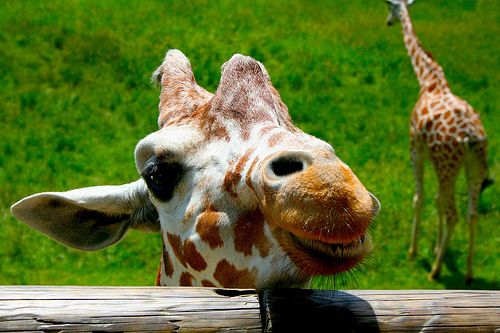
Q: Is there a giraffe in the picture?
A: Yes, there is a giraffe.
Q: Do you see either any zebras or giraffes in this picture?
A: Yes, there is a giraffe.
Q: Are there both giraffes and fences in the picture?
A: Yes, there are both a giraffe and a fence.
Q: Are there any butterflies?
A: No, there are no butterflies.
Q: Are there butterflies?
A: No, there are no butterflies.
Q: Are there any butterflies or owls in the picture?
A: No, there are no butterflies or owls.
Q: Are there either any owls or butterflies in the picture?
A: No, there are no butterflies or owls.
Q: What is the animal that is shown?
A: The animal is a giraffe.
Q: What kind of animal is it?
A: The animal is a giraffe.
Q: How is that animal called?
A: That is a giraffe.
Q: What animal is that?
A: That is a giraffe.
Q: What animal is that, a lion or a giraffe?
A: That is a giraffe.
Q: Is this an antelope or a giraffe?
A: This is a giraffe.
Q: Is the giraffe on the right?
A: Yes, the giraffe is on the right of the image.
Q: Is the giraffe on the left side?
A: No, the giraffe is on the right of the image.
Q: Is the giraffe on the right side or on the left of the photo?
A: The giraffe is on the right of the image.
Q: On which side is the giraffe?
A: The giraffe is on the right of the image.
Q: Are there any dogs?
A: No, there are no dogs.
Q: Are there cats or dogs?
A: No, there are no dogs or cats.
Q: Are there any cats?
A: No, there are no cats.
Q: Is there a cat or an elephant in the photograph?
A: No, there are no cats or elephants.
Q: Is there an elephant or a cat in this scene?
A: No, there are no cats or elephants.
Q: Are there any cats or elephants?
A: No, there are no cats or elephants.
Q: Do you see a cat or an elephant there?
A: No, there are no cats or elephants.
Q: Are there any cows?
A: No, there are no cows.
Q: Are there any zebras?
A: No, there are no zebras.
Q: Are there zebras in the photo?
A: No, there are no zebras.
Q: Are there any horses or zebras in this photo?
A: No, there are no zebras or horses.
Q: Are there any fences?
A: Yes, there is a fence.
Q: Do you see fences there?
A: Yes, there is a fence.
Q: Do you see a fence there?
A: Yes, there is a fence.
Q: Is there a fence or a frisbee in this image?
A: Yes, there is a fence.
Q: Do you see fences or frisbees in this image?
A: Yes, there is a fence.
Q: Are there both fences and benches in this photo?
A: No, there is a fence but no benches.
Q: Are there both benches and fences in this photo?
A: No, there is a fence but no benches.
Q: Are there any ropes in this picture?
A: No, there are no ropes.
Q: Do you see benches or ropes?
A: No, there are no ropes or benches.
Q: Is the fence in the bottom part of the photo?
A: Yes, the fence is in the bottom of the image.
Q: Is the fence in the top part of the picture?
A: No, the fence is in the bottom of the image.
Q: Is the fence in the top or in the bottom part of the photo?
A: The fence is in the bottom of the image.